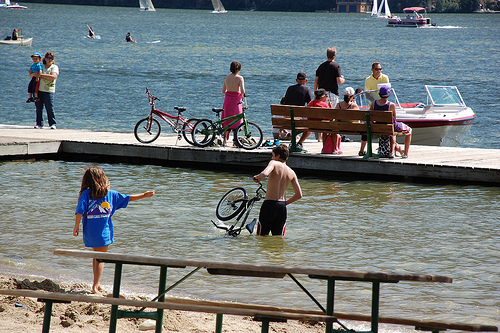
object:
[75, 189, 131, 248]
shirt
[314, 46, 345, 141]
man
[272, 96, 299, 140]
man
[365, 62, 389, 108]
man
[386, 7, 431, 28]
boat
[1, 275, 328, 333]
sand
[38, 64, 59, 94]
shirt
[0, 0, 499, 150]
ripples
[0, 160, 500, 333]
ripples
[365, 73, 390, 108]
shirt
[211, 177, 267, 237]
bike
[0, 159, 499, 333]
water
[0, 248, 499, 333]
picnic table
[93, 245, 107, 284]
legs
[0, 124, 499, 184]
dock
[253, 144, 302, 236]
boy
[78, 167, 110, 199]
hairs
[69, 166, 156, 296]
girl sand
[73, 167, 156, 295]
girl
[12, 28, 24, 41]
people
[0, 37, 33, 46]
boat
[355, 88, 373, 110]
people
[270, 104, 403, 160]
bench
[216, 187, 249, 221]
wheeel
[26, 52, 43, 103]
boy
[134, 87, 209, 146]
bike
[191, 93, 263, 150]
bike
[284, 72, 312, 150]
people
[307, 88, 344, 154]
people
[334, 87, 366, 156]
people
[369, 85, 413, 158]
people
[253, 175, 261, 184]
hand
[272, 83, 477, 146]
boat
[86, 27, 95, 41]
people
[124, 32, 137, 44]
people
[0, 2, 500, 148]
water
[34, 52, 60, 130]
people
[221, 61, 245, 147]
people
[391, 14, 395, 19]
people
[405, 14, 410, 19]
people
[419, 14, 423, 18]
people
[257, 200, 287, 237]
pants